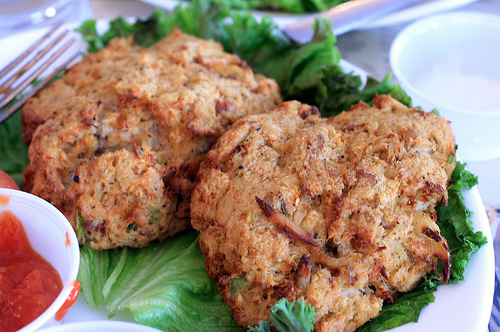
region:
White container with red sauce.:
[2, 175, 90, 330]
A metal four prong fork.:
[1, 13, 93, 123]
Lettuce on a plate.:
[238, 18, 373, 96]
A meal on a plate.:
[16, 29, 459, 329]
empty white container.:
[386, 8, 499, 168]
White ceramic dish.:
[447, 192, 498, 330]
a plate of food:
[5, 6, 497, 325]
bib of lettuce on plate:
[18, 8, 488, 321]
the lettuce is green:
[23, 2, 497, 324]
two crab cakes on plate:
[17, 13, 479, 330]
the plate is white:
[0, 10, 498, 327]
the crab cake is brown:
[166, 68, 488, 330]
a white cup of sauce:
[0, 168, 105, 330]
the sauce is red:
[2, 178, 103, 326]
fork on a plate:
[5, 8, 97, 122]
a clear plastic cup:
[379, 5, 499, 155]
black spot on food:
[235, 163, 244, 170]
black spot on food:
[234, 145, 242, 153]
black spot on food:
[253, 125, 261, 133]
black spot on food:
[303, 142, 310, 150]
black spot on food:
[302, 162, 307, 170]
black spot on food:
[315, 168, 322, 176]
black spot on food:
[338, 153, 345, 159]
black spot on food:
[288, 268, 298, 278]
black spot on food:
[73, 173, 83, 184]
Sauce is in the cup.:
[3, 174, 80, 330]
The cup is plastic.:
[1, 185, 77, 327]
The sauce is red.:
[0, 190, 82, 330]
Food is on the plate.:
[4, 23, 494, 330]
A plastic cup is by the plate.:
[387, 10, 499, 142]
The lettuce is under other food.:
[6, 22, 493, 330]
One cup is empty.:
[387, 4, 490, 159]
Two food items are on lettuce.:
[23, 22, 449, 330]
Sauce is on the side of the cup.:
[1, 184, 84, 330]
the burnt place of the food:
[248, 183, 328, 251]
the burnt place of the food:
[423, 224, 442, 244]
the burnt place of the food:
[439, 248, 459, 286]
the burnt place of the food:
[433, 176, 451, 211]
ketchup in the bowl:
[5, 200, 56, 302]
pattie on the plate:
[194, 91, 439, 313]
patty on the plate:
[13, 24, 259, 229]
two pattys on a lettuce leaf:
[41, 33, 441, 310]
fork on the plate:
[5, 24, 85, 121]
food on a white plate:
[28, 23, 450, 322]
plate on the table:
[19, 18, 478, 330]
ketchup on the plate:
[6, 223, 92, 313]